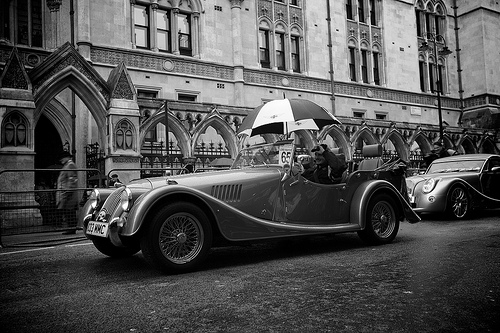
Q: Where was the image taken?
A: It was taken at the road.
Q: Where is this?
A: This is at the road.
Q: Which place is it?
A: It is a road.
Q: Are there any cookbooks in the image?
A: No, there are no cookbooks.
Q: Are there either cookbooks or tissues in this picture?
A: No, there are no cookbooks or tissues.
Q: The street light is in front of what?
A: The street light is in front of the building.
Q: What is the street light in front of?
A: The street light is in front of the building.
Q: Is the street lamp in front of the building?
A: Yes, the street lamp is in front of the building.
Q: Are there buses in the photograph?
A: No, there are no buses.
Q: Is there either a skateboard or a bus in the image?
A: No, there are no buses or skateboards.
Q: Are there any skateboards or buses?
A: No, there are no buses or skateboards.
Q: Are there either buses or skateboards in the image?
A: No, there are no buses or skateboards.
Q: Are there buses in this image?
A: No, there are no buses.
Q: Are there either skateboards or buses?
A: No, there are no buses or skateboards.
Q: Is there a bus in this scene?
A: No, there are no buses.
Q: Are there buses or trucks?
A: No, there are no buses or trucks.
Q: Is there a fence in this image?
A: Yes, there is a fence.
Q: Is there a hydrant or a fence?
A: Yes, there is a fence.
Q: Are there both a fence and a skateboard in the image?
A: No, there is a fence but no skateboards.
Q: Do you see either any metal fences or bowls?
A: Yes, there is a metal fence.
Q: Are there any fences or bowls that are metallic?
A: Yes, the fence is metallic.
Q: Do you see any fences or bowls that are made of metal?
A: Yes, the fence is made of metal.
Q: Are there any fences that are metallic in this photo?
A: Yes, there is a metal fence.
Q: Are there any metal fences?
A: Yes, there is a metal fence.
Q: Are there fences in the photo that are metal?
A: Yes, there is a metal fence.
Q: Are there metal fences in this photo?
A: Yes, there is a metal fence.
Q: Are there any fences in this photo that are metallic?
A: Yes, there is a fence that is metallic.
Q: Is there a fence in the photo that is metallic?
A: Yes, there is a fence that is metallic.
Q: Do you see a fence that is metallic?
A: Yes, there is a fence that is metallic.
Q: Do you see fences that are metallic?
A: Yes, there is a fence that is metallic.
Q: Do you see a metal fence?
A: Yes, there is a fence that is made of metal.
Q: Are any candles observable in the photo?
A: No, there are no candles.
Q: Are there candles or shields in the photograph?
A: No, there are no candles or shields.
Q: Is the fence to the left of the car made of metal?
A: Yes, the fence is made of metal.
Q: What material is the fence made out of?
A: The fence is made of metal.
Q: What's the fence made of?
A: The fence is made of metal.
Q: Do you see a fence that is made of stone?
A: No, there is a fence but it is made of metal.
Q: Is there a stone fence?
A: No, there is a fence but it is made of metal.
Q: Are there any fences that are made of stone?
A: No, there is a fence but it is made of metal.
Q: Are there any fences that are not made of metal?
A: No, there is a fence but it is made of metal.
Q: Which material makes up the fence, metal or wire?
A: The fence is made of metal.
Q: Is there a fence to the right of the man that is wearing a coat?
A: Yes, there is a fence to the right of the man.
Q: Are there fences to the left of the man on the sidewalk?
A: No, the fence is to the right of the man.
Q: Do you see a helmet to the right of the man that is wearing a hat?
A: No, there is a fence to the right of the man.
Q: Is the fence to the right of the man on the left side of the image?
A: Yes, the fence is to the right of the man.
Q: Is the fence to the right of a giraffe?
A: No, the fence is to the right of the man.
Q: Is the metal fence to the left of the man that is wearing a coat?
A: No, the fence is to the right of the man.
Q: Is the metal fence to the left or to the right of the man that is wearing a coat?
A: The fence is to the right of the man.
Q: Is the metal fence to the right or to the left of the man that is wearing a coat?
A: The fence is to the right of the man.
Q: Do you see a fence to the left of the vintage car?
A: Yes, there is a fence to the left of the car.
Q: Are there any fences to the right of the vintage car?
A: No, the fence is to the left of the car.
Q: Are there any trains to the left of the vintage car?
A: No, there is a fence to the left of the car.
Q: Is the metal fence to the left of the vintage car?
A: Yes, the fence is to the left of the car.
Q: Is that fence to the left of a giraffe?
A: No, the fence is to the left of the car.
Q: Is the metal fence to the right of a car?
A: No, the fence is to the left of a car.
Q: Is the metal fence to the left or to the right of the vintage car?
A: The fence is to the left of the car.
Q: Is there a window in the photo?
A: Yes, there is a window.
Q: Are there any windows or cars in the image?
A: Yes, there is a window.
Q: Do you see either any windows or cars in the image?
A: Yes, there is a window.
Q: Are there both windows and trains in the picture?
A: No, there is a window but no trains.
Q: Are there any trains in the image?
A: No, there are no trains.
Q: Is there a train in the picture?
A: No, there are no trains.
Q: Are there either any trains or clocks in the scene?
A: No, there are no trains or clocks.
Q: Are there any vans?
A: No, there are no vans.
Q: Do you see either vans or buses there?
A: No, there are no vans or buses.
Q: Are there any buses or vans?
A: No, there are no vans or buses.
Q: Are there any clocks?
A: No, there are no clocks.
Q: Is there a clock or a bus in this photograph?
A: No, there are no clocks or buses.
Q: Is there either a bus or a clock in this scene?
A: No, there are no clocks or buses.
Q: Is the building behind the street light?
A: Yes, the building is behind the street light.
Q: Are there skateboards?
A: No, there are no skateboards.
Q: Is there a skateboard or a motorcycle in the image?
A: No, there are no skateboards or motorcycles.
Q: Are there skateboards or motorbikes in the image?
A: No, there are no skateboards or motorbikes.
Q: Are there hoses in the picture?
A: No, there are no hoses.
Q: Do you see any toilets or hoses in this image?
A: No, there are no hoses or toilets.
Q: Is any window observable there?
A: Yes, there is a window.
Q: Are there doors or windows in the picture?
A: Yes, there is a window.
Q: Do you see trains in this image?
A: No, there are no trains.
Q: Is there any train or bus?
A: No, there are no trains or buses.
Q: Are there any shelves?
A: No, there are no shelves.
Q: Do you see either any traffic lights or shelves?
A: No, there are no shelves or traffic lights.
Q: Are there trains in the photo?
A: No, there are no trains.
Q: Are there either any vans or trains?
A: No, there are no trains or vans.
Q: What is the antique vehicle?
A: The vehicle is a car.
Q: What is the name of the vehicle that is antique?
A: The vehicle is a car.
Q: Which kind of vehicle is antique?
A: The vehicle is a car.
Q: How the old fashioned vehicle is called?
A: The vehicle is a car.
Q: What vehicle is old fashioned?
A: The vehicle is a car.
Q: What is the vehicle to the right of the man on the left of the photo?
A: The vehicle is a car.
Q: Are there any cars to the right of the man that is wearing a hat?
A: Yes, there is a car to the right of the man.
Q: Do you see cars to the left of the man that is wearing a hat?
A: No, the car is to the right of the man.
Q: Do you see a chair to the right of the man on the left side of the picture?
A: No, there is a car to the right of the man.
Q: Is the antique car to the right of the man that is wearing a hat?
A: Yes, the car is to the right of the man.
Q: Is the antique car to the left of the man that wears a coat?
A: No, the car is to the right of the man.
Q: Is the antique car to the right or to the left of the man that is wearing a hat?
A: The car is to the right of the man.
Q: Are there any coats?
A: Yes, there is a coat.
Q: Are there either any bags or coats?
A: Yes, there is a coat.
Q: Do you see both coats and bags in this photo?
A: No, there is a coat but no bags.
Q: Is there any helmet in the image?
A: No, there are no helmets.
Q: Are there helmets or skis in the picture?
A: No, there are no helmets or skis.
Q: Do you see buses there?
A: No, there are no buses.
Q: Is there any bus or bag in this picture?
A: No, there are no buses or bags.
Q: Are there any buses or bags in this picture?
A: No, there are no buses or bags.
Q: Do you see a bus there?
A: No, there are no buses.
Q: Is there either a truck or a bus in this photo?
A: No, there are no buses or trucks.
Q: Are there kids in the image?
A: No, there are no kids.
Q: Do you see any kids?
A: No, there are no kids.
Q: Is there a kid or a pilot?
A: No, there are no children or pilots.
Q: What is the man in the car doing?
A: The man is driving.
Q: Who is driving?
A: The man is driving.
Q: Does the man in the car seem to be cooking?
A: No, the man is driving.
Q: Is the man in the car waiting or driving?
A: The man is driving.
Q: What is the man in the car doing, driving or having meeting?
A: The man is driving.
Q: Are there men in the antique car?
A: Yes, there is a man in the car.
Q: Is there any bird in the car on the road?
A: No, there is a man in the car.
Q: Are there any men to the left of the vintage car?
A: Yes, there is a man to the left of the car.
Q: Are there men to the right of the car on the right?
A: No, the man is to the left of the car.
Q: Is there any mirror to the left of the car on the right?
A: No, there is a man to the left of the car.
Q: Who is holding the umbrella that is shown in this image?
A: The man is holding the umbrella.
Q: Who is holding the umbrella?
A: The man is holding the umbrella.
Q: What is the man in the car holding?
A: The man is holding the umbrella.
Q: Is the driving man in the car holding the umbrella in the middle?
A: Yes, the man is holding the umbrella.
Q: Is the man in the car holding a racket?
A: No, the man is holding the umbrella.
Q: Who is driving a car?
A: The man is driving a car.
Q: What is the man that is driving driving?
A: The man is driving a car.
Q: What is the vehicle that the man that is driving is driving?
A: The vehicle is a car.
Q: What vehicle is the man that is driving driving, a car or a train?
A: The man is driving a car.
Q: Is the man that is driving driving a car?
A: Yes, the man is driving a car.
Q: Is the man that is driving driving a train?
A: No, the man is driving a car.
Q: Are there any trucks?
A: No, there are no trucks.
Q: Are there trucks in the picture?
A: No, there are no trucks.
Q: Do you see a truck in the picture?
A: No, there are no trucks.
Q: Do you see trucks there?
A: No, there are no trucks.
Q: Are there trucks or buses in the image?
A: No, there are no trucks or buses.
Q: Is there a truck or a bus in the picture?
A: No, there are no trucks or buses.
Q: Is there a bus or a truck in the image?
A: No, there are no trucks or buses.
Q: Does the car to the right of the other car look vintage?
A: Yes, the car is vintage.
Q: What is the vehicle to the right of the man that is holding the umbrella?
A: The vehicle is a car.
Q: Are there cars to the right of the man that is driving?
A: Yes, there is a car to the right of the man.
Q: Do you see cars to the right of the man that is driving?
A: Yes, there is a car to the right of the man.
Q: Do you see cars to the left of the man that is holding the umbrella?
A: No, the car is to the right of the man.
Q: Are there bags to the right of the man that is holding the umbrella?
A: No, there is a car to the right of the man.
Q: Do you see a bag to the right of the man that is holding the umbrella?
A: No, there is a car to the right of the man.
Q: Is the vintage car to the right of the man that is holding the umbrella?
A: Yes, the car is to the right of the man.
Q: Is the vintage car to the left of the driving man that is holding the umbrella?
A: No, the car is to the right of the man.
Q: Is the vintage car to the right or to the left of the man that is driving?
A: The car is to the right of the man.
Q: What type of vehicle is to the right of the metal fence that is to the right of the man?
A: The vehicle is a car.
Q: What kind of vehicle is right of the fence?
A: The vehicle is a car.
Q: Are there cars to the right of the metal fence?
A: Yes, there is a car to the right of the fence.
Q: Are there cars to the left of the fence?
A: No, the car is to the right of the fence.